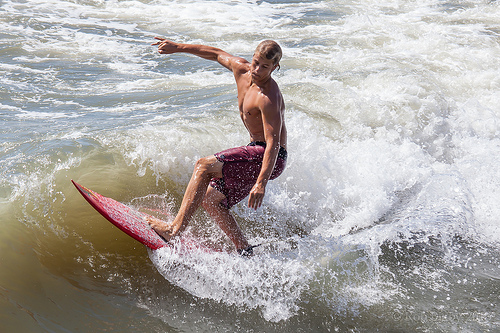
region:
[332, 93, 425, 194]
sea foam on top of wave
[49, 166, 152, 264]
red and white surf board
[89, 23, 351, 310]
man on red surf board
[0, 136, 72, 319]
wave forming on top of water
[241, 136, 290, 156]
black belt on waist of surfer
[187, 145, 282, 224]
red swimming trunks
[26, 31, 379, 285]
man balancing on surf board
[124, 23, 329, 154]
shirtless man on surfboard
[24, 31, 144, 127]
small ripples on water surface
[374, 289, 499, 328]
name of photographer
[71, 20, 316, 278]
The man is on a surfboard.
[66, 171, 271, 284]
The surfboard is red.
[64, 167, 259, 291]
The surfboard is wet.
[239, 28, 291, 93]
The man has hair.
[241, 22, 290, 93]
The hair is blonde.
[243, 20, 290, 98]
The hair is wet.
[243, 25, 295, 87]
The hair is short.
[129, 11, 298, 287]
The man is standing.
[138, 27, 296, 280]
The man is tanned.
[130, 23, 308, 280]
The man is wearing swimming trunks.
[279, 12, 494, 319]
breaking waves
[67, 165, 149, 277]
tip of red surfboard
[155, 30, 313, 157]
shirtless blonde man on water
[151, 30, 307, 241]
shirtless man wearing red shorts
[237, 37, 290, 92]
blonde man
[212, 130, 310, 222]
man's red shorts worn in water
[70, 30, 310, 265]
shirtless man catching a wave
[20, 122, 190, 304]
wave breaking around surfboard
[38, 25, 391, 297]
man surfing riding wave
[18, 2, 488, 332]
young surfer surrounded by breaking water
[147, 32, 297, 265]
surfer on surf board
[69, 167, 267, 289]
red surfboard in water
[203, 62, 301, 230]
surfer in red shorts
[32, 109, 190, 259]
wave the surfer is surfing on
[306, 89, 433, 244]
white splash from waves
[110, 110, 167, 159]
white foam from waves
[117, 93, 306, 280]
man surfing barefoot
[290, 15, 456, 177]
waving water that is rough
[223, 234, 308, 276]
strap for surfboard on man ankle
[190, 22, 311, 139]
man with hair slicked back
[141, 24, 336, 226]
a surfer surfing on waves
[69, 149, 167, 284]
the red surf board of the surfer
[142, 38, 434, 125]
the hair of the surfer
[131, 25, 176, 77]
hand of the surfer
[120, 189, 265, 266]
the feet of the surfer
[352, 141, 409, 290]
the waves in the ocean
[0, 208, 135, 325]
the nice ocean water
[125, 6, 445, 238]
the surfer having fun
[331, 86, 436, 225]
the nice white waves coming up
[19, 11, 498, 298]
a surf scene